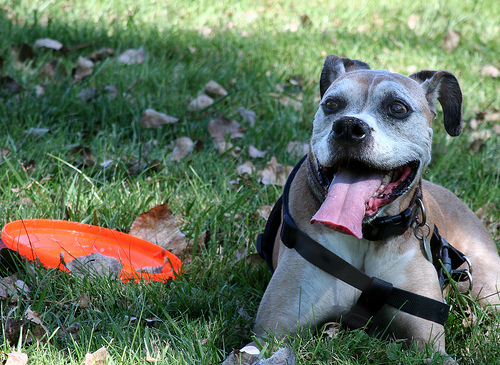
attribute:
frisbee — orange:
[1, 217, 184, 285]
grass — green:
[2, 1, 500, 364]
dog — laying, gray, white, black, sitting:
[240, 55, 499, 364]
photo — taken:
[2, 2, 500, 364]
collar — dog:
[307, 152, 426, 242]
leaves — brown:
[141, 79, 244, 167]